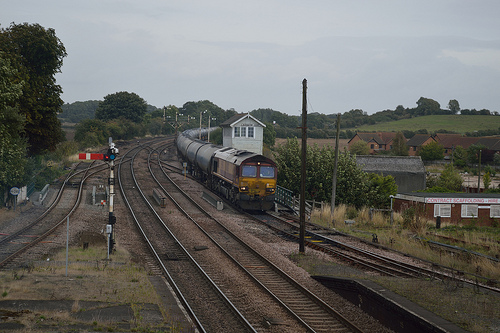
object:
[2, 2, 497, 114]
sky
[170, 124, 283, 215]
train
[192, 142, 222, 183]
tanks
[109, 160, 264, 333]
tracks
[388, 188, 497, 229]
buildings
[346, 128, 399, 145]
roofs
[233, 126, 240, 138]
windows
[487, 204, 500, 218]
windows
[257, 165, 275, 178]
windows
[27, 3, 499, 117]
cloud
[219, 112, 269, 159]
building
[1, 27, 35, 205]
tree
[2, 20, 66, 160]
tree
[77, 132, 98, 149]
tree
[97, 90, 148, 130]
tree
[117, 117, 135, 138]
tree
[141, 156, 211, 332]
train tracks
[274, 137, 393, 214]
bush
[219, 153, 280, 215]
engine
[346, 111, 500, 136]
hilltop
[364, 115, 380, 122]
shrubs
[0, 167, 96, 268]
tracks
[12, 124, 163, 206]
edge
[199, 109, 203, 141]
pole